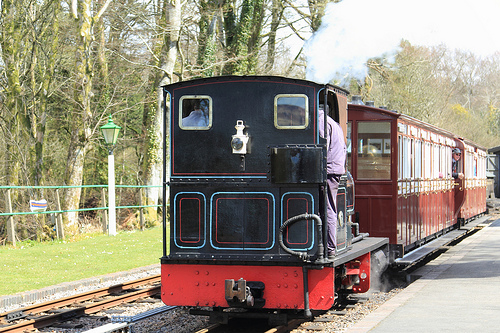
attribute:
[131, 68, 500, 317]
train — multicolored, long, black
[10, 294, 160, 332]
tracks — metal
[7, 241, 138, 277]
grass — green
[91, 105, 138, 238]
lamp — green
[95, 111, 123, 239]
post — short, white, muticolored, wooden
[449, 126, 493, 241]
car — farther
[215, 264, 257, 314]
hitch — empty, metal, unused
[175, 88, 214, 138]
window — glass, clear, square, small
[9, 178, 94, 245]
fence — green, metal, leaning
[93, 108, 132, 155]
lamp — metal, glass